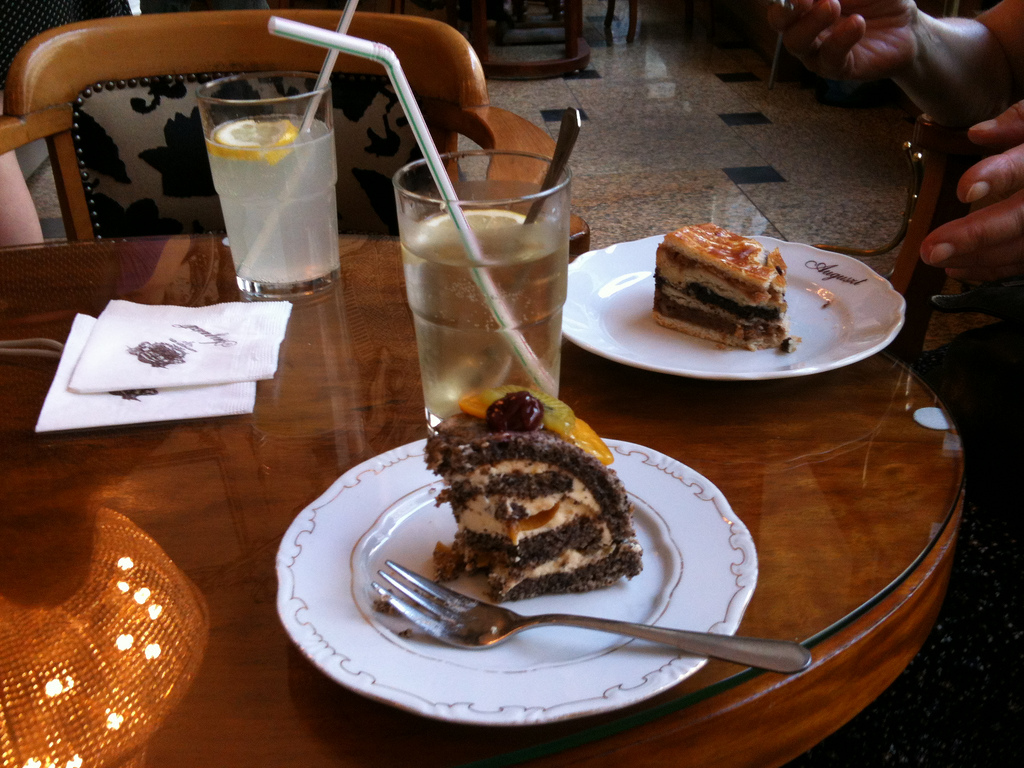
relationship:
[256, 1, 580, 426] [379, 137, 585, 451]
straw in drink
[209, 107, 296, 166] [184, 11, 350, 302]
lemon slice in drink